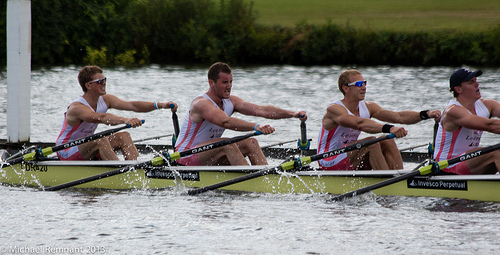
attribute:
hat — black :
[448, 65, 472, 85]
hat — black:
[444, 63, 484, 88]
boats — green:
[10, 138, 492, 210]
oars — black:
[19, 95, 495, 210]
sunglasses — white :
[86, 77, 108, 86]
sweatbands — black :
[378, 118, 395, 133]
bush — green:
[145, 0, 251, 72]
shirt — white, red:
[53, 99, 139, 152]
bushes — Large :
[34, 5, 263, 62]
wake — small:
[1, 181, 379, 211]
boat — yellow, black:
[2, 138, 499, 202]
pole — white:
[5, 0, 31, 142]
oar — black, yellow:
[4, 118, 146, 168]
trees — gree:
[36, 2, 233, 55]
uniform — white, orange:
[54, 96, 111, 162]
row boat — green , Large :
[0, 140, 500, 204]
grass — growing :
[252, 7, 497, 34]